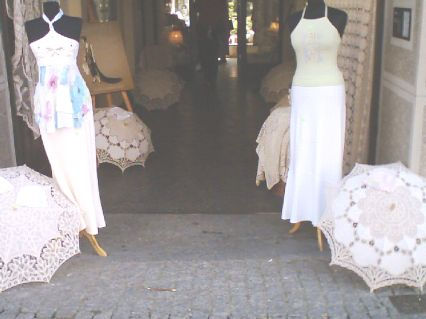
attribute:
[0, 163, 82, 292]
umbrella — white, pink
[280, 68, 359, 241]
skirt — white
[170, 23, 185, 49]
light — white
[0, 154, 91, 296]
umbrella — open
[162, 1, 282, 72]
doorway — open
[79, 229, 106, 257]
wood — piece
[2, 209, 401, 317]
walkway — brick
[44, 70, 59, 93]
design — in middle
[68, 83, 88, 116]
design — in middle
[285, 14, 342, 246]
dress — white, blue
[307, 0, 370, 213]
wall — white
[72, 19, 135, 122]
easel — wooden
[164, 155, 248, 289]
sidewalk — light grey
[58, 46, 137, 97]
stand — wood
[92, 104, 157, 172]
umbrella — open, white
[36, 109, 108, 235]
whit skirt — white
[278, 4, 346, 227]
dress — yellow, white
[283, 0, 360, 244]
mannequin — black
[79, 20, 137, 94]
portrait — oil, of woman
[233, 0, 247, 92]
pillar — strong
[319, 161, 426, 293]
umbrella — open, pink, white, black, brown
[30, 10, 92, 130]
tank — rainbow 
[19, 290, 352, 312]
ground — cobble stone